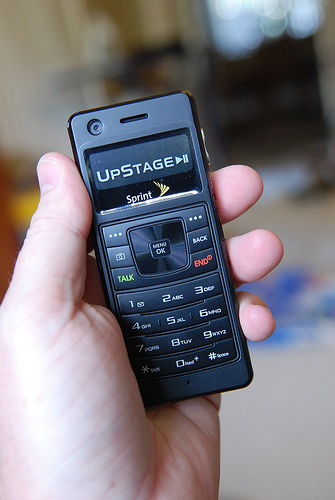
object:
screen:
[82, 125, 204, 214]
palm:
[0, 294, 227, 497]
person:
[0, 147, 286, 498]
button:
[147, 237, 173, 260]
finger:
[225, 227, 285, 285]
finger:
[236, 291, 276, 342]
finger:
[4, 149, 94, 303]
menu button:
[147, 238, 171, 258]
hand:
[0, 139, 284, 498]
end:
[193, 255, 210, 270]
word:
[192, 233, 207, 245]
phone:
[65, 89, 255, 411]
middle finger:
[207, 164, 264, 224]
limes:
[115, 270, 218, 298]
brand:
[151, 180, 171, 202]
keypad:
[116, 272, 238, 383]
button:
[188, 246, 219, 279]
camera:
[86, 118, 105, 137]